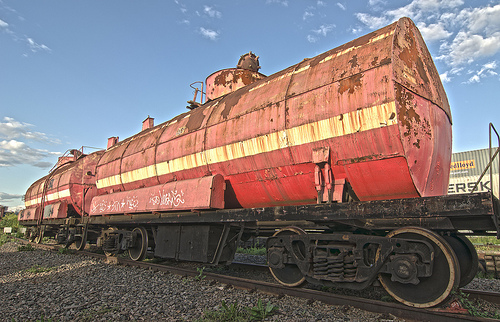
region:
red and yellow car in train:
[188, 90, 415, 184]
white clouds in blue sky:
[9, 4, 79, 74]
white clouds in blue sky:
[16, 91, 88, 136]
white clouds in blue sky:
[62, 16, 129, 70]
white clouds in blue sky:
[81, 63, 126, 114]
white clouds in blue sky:
[143, 11, 188, 78]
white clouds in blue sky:
[202, 4, 236, 42]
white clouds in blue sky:
[236, 11, 274, 39]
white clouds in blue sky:
[418, 6, 498, 58]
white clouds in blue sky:
[453, 50, 495, 121]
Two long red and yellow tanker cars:
[35, 45, 445, 250]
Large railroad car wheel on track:
[370, 228, 455, 299]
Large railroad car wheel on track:
[263, 231, 313, 292]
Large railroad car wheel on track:
[128, 230, 158, 259]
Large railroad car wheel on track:
[93, 228, 125, 256]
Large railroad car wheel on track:
[71, 218, 95, 250]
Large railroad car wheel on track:
[37, 223, 46, 250]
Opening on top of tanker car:
[214, 46, 274, 83]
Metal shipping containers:
[446, 159, 498, 224]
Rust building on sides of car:
[394, 48, 429, 135]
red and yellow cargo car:
[83, 37, 424, 210]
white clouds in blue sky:
[6, 9, 54, 43]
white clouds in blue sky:
[17, 59, 58, 100]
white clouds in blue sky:
[14, 104, 56, 129]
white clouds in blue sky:
[260, 6, 300, 47]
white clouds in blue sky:
[455, 33, 487, 80]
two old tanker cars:
[28, 13, 498, 308]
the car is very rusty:
[43, 33, 423, 227]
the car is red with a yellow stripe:
[54, 15, 456, 250]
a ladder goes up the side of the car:
[23, 153, 63, 218]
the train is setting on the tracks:
[102, 233, 469, 318]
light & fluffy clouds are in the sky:
[423, 2, 494, 87]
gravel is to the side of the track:
[43, 260, 154, 316]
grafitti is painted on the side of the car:
[91, 186, 208, 208]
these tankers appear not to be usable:
[16, 1, 466, 276]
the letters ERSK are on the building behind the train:
[448, 168, 491, 200]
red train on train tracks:
[23, 23, 493, 310]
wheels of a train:
[252, 230, 482, 313]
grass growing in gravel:
[221, 302, 293, 317]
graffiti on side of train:
[93, 180, 203, 210]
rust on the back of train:
[395, 29, 453, 159]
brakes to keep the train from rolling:
[426, 299, 473, 309]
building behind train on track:
[445, 153, 495, 189]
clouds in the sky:
[0, 113, 56, 165]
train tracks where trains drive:
[225, 268, 496, 313]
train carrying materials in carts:
[18, 89, 463, 204]